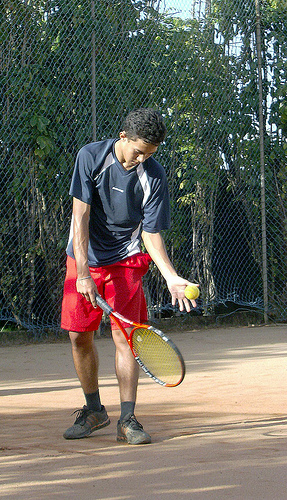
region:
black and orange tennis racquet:
[94, 294, 184, 388]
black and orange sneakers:
[64, 407, 150, 446]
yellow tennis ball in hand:
[183, 285, 198, 297]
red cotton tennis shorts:
[62, 251, 151, 333]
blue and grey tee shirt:
[63, 140, 167, 260]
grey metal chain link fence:
[1, 0, 285, 328]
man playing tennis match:
[58, 110, 198, 442]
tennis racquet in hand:
[77, 283, 187, 392]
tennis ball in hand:
[170, 281, 199, 311]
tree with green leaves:
[2, 0, 86, 342]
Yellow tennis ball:
[184, 284, 199, 299]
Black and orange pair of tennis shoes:
[60, 404, 151, 443]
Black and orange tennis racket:
[93, 293, 186, 388]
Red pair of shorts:
[60, 253, 148, 330]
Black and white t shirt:
[65, 138, 168, 265]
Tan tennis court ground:
[0, 325, 286, 498]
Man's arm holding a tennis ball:
[139, 230, 198, 311]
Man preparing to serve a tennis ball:
[61, 107, 199, 443]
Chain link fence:
[0, 0, 286, 337]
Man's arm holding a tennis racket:
[69, 196, 99, 310]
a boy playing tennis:
[25, 82, 254, 498]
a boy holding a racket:
[40, 108, 226, 447]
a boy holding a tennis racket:
[27, 105, 283, 433]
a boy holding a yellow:
[65, 96, 246, 348]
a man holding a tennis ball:
[31, 107, 250, 358]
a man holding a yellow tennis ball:
[53, 100, 239, 322]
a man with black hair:
[46, 94, 216, 314]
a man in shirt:
[25, 81, 223, 334]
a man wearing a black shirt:
[51, 88, 227, 316]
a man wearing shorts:
[36, 72, 217, 397]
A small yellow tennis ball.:
[181, 279, 200, 304]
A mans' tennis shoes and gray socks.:
[63, 397, 151, 449]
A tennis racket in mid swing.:
[92, 291, 191, 389]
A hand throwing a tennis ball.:
[135, 231, 203, 315]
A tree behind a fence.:
[13, 113, 63, 257]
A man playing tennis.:
[36, 104, 212, 445]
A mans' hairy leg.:
[59, 332, 106, 402]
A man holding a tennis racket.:
[71, 258, 180, 394]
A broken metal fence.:
[159, 302, 235, 327]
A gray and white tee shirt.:
[61, 156, 173, 264]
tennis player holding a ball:
[95, 111, 194, 314]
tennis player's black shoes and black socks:
[64, 392, 149, 443]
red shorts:
[121, 262, 145, 320]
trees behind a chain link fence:
[7, 11, 89, 127]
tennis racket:
[92, 293, 183, 388]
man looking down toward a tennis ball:
[71, 108, 196, 317]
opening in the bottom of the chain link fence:
[210, 294, 271, 321]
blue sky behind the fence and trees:
[174, 2, 190, 9]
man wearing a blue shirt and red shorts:
[71, 116, 160, 332]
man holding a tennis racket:
[76, 109, 186, 388]